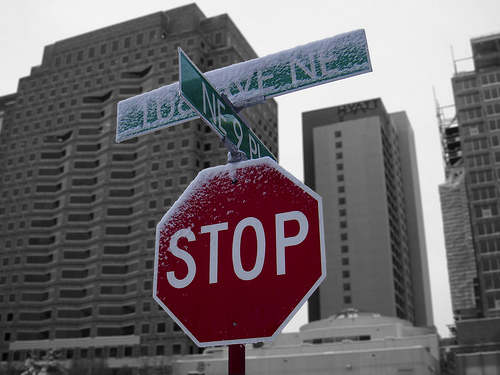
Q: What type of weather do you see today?
A: It is cloudy.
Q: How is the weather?
A: It is cloudy.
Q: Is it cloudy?
A: Yes, it is cloudy.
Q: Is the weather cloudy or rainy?
A: It is cloudy.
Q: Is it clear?
A: No, it is cloudy.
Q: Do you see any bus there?
A: No, there are no buses.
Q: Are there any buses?
A: No, there are no buses.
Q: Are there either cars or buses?
A: No, there are no buses or cars.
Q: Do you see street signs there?
A: Yes, there is a street sign.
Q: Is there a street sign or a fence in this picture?
A: Yes, there is a street sign.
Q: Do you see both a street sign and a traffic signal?
A: No, there is a street sign but no traffic lights.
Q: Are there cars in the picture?
A: No, there are no cars.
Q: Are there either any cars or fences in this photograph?
A: No, there are no cars or fences.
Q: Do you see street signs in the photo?
A: Yes, there is a street sign.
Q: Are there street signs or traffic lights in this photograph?
A: Yes, there is a street sign.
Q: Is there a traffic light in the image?
A: No, there are no traffic lights.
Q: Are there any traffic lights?
A: No, there are no traffic lights.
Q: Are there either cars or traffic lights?
A: No, there are no traffic lights or cars.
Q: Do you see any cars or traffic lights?
A: No, there are no traffic lights or cars.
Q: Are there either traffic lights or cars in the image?
A: No, there are no traffic lights or cars.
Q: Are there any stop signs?
A: Yes, there is a stop sign.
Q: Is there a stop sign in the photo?
A: Yes, there is a stop sign.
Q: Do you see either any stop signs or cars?
A: Yes, there is a stop sign.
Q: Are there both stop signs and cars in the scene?
A: No, there is a stop sign but no cars.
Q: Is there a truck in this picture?
A: No, there are no trucks.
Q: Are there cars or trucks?
A: No, there are no trucks or cars.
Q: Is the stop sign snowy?
A: Yes, the stop sign is snowy.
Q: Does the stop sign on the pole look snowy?
A: Yes, the stop sign is snowy.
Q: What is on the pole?
A: The stop sign is on the pole.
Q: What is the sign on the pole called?
A: The sign is a stop sign.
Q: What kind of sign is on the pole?
A: The sign is a stop sign.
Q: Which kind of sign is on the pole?
A: The sign is a stop sign.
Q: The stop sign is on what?
A: The stop sign is on the pole.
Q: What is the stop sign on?
A: The stop sign is on the pole.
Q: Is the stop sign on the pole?
A: Yes, the stop sign is on the pole.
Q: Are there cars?
A: No, there are no cars.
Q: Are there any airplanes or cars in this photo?
A: No, there are no cars or airplanes.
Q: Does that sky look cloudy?
A: Yes, the sky is cloudy.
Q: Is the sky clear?
A: No, the sky is cloudy.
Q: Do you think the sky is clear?
A: No, the sky is cloudy.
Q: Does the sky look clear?
A: No, the sky is cloudy.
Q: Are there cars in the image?
A: No, there are no cars.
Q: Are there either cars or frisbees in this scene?
A: No, there are no cars or frisbees.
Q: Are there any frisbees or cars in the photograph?
A: No, there are no cars or frisbees.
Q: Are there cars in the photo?
A: No, there are no cars.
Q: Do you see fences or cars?
A: No, there are no cars or fences.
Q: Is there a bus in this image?
A: No, there are no buses.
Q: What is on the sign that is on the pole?
A: The word is on the stop sign.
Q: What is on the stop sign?
A: The word is on the stop sign.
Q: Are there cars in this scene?
A: No, there are no cars.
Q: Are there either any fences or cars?
A: No, there are no cars or fences.